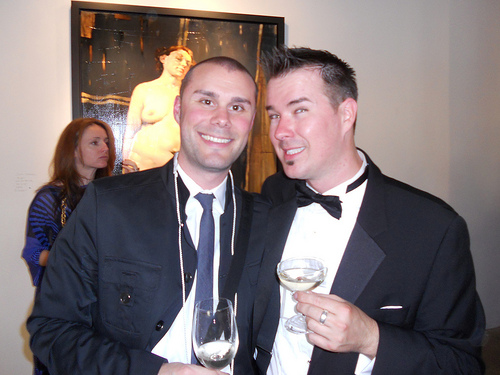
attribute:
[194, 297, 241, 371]
glass — large, empty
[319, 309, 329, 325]
band — silver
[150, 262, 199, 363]
handkerchief — white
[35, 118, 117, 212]
hair — long, down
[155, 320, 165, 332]
button — black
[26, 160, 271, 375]
jacket — blue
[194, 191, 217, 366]
tie — long, blue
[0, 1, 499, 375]
wall — bright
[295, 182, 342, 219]
bow tie — black, formal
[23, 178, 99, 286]
outfit — striped, blue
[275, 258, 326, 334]
drink — small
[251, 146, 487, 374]
suit — formal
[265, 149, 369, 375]
shirt — white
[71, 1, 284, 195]
frame — brown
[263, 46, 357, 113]
hair — spiked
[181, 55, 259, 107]
hair — cropped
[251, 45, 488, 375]
man — here